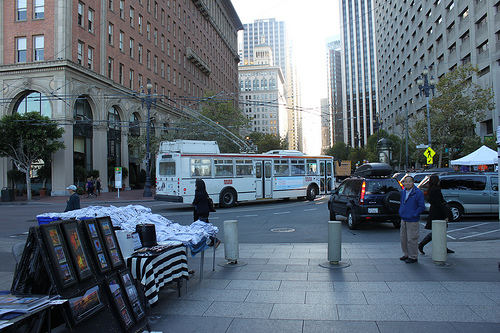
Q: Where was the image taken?
A: It was taken at the sidewalk.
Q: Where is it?
A: This is at the sidewalk.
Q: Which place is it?
A: It is a sidewalk.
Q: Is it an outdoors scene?
A: Yes, it is outdoors.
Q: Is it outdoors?
A: Yes, it is outdoors.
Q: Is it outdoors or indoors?
A: It is outdoors.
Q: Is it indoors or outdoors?
A: It is outdoors.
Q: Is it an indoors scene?
A: No, it is outdoors.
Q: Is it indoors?
A: No, it is outdoors.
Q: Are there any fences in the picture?
A: No, there are no fences.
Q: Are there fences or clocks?
A: No, there are no fences or clocks.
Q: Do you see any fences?
A: No, there are no fences.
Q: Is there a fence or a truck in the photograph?
A: No, there are no fences or trucks.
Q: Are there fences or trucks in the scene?
A: No, there are no fences or trucks.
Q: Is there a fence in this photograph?
A: No, there are no fences.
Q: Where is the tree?
A: The tree is on the street.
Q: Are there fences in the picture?
A: No, there are no fences.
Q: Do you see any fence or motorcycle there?
A: No, there are no fences or motorcycles.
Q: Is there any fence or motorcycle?
A: No, there are no fences or motorcycles.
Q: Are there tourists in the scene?
A: No, there are no tourists.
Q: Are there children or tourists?
A: No, there are no tourists or children.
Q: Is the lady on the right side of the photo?
A: Yes, the lady is on the right of the image.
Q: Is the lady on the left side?
A: No, the lady is on the right of the image.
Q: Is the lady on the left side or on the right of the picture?
A: The lady is on the right of the image.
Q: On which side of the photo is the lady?
A: The lady is on the right of the image.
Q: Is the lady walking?
A: Yes, the lady is walking.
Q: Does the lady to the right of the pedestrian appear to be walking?
A: Yes, the lady is walking.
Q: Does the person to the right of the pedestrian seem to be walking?
A: Yes, the lady is walking.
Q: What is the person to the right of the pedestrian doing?
A: The lady is walking.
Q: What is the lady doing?
A: The lady is walking.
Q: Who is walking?
A: The lady is walking.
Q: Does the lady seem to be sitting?
A: No, the lady is walking.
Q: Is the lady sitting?
A: No, the lady is walking.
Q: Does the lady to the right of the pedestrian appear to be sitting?
A: No, the lady is walking.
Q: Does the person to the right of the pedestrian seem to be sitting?
A: No, the lady is walking.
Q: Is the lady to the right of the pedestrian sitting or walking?
A: The lady is walking.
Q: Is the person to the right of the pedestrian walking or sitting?
A: The lady is walking.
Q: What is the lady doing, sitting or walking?
A: The lady is walking.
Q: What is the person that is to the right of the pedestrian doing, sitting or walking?
A: The lady is walking.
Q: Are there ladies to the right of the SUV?
A: Yes, there is a lady to the right of the SUV.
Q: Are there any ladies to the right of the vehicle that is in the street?
A: Yes, there is a lady to the right of the SUV.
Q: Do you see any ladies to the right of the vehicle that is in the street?
A: Yes, there is a lady to the right of the SUV.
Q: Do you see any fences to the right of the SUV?
A: No, there is a lady to the right of the SUV.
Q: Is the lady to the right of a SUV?
A: Yes, the lady is to the right of a SUV.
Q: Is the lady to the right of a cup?
A: No, the lady is to the right of a SUV.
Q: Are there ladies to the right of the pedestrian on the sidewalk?
A: Yes, there is a lady to the right of the pedestrian.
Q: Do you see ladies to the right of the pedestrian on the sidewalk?
A: Yes, there is a lady to the right of the pedestrian.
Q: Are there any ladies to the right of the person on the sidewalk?
A: Yes, there is a lady to the right of the pedestrian.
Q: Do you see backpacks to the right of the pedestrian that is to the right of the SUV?
A: No, there is a lady to the right of the pedestrian.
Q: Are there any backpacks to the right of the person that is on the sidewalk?
A: No, there is a lady to the right of the pedestrian.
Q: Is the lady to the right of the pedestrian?
A: Yes, the lady is to the right of the pedestrian.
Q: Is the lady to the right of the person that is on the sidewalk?
A: Yes, the lady is to the right of the pedestrian.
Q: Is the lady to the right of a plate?
A: No, the lady is to the right of the pedestrian.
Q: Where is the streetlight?
A: The streetlight is on the street.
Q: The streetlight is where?
A: The streetlight is on the street.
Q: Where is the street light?
A: The streetlight is on the street.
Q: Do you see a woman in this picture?
A: Yes, there is a woman.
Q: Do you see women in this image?
A: Yes, there is a woman.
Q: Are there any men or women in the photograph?
A: Yes, there is a woman.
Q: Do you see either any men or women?
A: Yes, there is a woman.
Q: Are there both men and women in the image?
A: Yes, there are both a woman and a man.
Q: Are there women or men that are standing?
A: Yes, the woman is standing.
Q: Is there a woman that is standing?
A: Yes, there is a woman that is standing.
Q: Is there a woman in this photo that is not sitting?
A: Yes, there is a woman that is standing.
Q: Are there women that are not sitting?
A: Yes, there is a woman that is standing.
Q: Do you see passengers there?
A: No, there are no passengers.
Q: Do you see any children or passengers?
A: No, there are no passengers or children.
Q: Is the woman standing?
A: Yes, the woman is standing.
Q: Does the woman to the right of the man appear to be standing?
A: Yes, the woman is standing.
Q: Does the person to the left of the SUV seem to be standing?
A: Yes, the woman is standing.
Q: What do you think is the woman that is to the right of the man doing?
A: The woman is standing.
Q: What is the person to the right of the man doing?
A: The woman is standing.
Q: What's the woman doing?
A: The woman is standing.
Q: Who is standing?
A: The woman is standing.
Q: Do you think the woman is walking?
A: No, the woman is standing.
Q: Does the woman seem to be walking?
A: No, the woman is standing.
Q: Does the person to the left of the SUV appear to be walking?
A: No, the woman is standing.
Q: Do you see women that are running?
A: No, there is a woman but she is standing.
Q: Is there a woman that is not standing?
A: No, there is a woman but she is standing.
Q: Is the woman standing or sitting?
A: The woman is standing.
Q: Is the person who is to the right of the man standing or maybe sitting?
A: The woman is standing.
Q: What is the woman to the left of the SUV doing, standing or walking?
A: The woman is standing.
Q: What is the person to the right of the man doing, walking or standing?
A: The woman is standing.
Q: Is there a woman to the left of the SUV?
A: Yes, there is a woman to the left of the SUV.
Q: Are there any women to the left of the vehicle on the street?
A: Yes, there is a woman to the left of the SUV.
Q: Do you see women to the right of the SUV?
A: No, the woman is to the left of the SUV.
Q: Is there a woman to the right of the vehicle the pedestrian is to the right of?
A: No, the woman is to the left of the SUV.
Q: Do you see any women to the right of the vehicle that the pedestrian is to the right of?
A: No, the woman is to the left of the SUV.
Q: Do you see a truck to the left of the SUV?
A: No, there is a woman to the left of the SUV.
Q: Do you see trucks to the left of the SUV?
A: No, there is a woman to the left of the SUV.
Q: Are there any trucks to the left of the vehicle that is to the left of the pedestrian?
A: No, there is a woman to the left of the SUV.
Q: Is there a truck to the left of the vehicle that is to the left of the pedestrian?
A: No, there is a woman to the left of the SUV.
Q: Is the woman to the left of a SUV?
A: Yes, the woman is to the left of a SUV.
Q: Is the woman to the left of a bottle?
A: No, the woman is to the left of a SUV.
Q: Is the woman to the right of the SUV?
A: No, the woman is to the left of the SUV.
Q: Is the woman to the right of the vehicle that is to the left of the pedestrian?
A: No, the woman is to the left of the SUV.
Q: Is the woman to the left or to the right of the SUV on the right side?
A: The woman is to the left of the SUV.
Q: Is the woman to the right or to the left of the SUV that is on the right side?
A: The woman is to the left of the SUV.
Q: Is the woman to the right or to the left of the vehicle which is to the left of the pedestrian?
A: The woman is to the left of the SUV.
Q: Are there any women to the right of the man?
A: Yes, there is a woman to the right of the man.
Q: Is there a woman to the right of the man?
A: Yes, there is a woman to the right of the man.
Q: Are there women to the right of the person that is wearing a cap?
A: Yes, there is a woman to the right of the man.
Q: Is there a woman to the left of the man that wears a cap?
A: No, the woman is to the right of the man.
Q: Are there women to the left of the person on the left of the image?
A: No, the woman is to the right of the man.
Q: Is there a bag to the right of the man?
A: No, there is a woman to the right of the man.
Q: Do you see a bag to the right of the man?
A: No, there is a woman to the right of the man.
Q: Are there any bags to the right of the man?
A: No, there is a woman to the right of the man.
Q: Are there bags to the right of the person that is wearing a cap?
A: No, there is a woman to the right of the man.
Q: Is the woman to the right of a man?
A: Yes, the woman is to the right of a man.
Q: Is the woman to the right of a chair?
A: No, the woman is to the right of a man.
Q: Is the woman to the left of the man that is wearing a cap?
A: No, the woman is to the right of the man.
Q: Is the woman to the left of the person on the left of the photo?
A: No, the woman is to the right of the man.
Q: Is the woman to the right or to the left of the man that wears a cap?
A: The woman is to the right of the man.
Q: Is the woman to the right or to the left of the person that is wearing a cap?
A: The woman is to the right of the man.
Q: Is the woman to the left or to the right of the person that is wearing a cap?
A: The woman is to the right of the man.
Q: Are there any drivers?
A: No, there are no drivers.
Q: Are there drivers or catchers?
A: No, there are no drivers or catchers.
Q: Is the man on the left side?
A: Yes, the man is on the left of the image.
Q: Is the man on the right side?
A: No, the man is on the left of the image.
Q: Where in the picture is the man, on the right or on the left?
A: The man is on the left of the image.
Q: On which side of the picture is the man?
A: The man is on the left of the image.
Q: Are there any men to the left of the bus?
A: Yes, there is a man to the left of the bus.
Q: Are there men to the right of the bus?
A: No, the man is to the left of the bus.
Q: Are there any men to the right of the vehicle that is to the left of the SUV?
A: No, the man is to the left of the bus.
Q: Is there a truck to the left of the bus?
A: No, there is a man to the left of the bus.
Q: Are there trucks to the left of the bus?
A: No, there is a man to the left of the bus.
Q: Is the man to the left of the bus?
A: Yes, the man is to the left of the bus.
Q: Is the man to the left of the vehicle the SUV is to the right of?
A: Yes, the man is to the left of the bus.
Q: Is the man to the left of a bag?
A: No, the man is to the left of the bus.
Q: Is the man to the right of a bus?
A: No, the man is to the left of a bus.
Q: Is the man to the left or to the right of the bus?
A: The man is to the left of the bus.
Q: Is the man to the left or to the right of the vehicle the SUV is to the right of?
A: The man is to the left of the bus.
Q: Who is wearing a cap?
A: The man is wearing a cap.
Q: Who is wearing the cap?
A: The man is wearing a cap.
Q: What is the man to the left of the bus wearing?
A: The man is wearing a cap.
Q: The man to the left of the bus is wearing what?
A: The man is wearing a cap.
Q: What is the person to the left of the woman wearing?
A: The man is wearing a cap.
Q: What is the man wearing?
A: The man is wearing a cap.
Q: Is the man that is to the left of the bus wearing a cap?
A: Yes, the man is wearing a cap.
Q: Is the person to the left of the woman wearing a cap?
A: Yes, the man is wearing a cap.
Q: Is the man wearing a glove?
A: No, the man is wearing a cap.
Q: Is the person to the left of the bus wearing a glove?
A: No, the man is wearing a cap.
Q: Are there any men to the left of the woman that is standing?
A: Yes, there is a man to the left of the woman.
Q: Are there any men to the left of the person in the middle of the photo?
A: Yes, there is a man to the left of the woman.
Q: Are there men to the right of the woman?
A: No, the man is to the left of the woman.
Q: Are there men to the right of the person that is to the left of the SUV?
A: No, the man is to the left of the woman.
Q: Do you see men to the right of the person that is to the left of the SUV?
A: No, the man is to the left of the woman.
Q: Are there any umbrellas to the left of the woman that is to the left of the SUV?
A: No, there is a man to the left of the woman.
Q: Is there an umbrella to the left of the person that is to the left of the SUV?
A: No, there is a man to the left of the woman.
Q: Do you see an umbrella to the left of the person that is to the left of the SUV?
A: No, there is a man to the left of the woman.